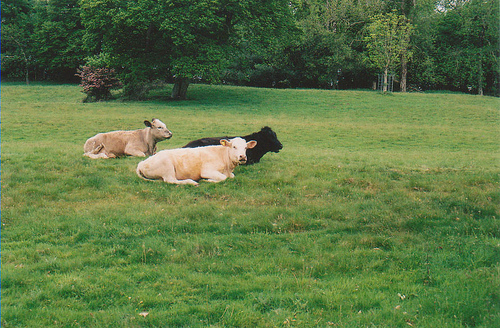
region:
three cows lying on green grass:
[75, 107, 286, 192]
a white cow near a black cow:
[132, 135, 258, 189]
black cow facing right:
[179, 120, 288, 163]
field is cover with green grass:
[5, 86, 495, 326]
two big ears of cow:
[215, 135, 260, 150]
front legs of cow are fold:
[202, 170, 240, 187]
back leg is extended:
[160, 166, 202, 189]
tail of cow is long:
[129, 165, 165, 185]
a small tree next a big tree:
[77, 50, 127, 106]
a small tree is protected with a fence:
[358, 12, 414, 93]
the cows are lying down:
[78, 107, 313, 208]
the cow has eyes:
[230, 138, 248, 153]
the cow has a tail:
[122, 159, 159, 186]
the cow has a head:
[132, 109, 177, 146]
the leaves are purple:
[65, 51, 124, 97]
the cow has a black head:
[255, 116, 295, 163]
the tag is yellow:
[215, 134, 227, 146]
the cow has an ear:
[249, 134, 260, 157]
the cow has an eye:
[149, 119, 166, 136]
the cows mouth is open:
[270, 140, 292, 157]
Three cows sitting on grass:
[50, 82, 291, 193]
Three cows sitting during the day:
[53, 87, 288, 195]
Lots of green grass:
[311, 127, 479, 297]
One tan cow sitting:
[76, 106, 181, 159]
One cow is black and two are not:
[73, 112, 290, 189]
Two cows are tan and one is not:
[103, 118, 290, 183]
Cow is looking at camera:
[218, 130, 249, 170]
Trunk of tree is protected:
[370, 65, 401, 97]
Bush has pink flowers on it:
[76, 53, 123, 106]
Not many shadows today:
[106, 9, 263, 108]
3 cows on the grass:
[35, 92, 322, 237]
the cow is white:
[122, 137, 252, 195]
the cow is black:
[256, 105, 296, 177]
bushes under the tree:
[49, 47, 126, 103]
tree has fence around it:
[348, 64, 405, 101]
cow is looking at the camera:
[210, 125, 262, 177]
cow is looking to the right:
[132, 92, 181, 147]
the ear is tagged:
[211, 132, 229, 149]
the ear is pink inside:
[244, 135, 259, 149]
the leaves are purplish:
[57, 47, 122, 104]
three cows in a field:
[61, 92, 332, 200]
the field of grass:
[14, 88, 421, 319]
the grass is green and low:
[31, 78, 497, 327]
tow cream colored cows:
[68, 109, 256, 206]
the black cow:
[183, 127, 290, 168]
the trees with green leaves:
[29, 5, 471, 77]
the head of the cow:
[216, 133, 265, 167]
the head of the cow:
[262, 120, 294, 157]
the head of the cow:
[136, 110, 173, 142]